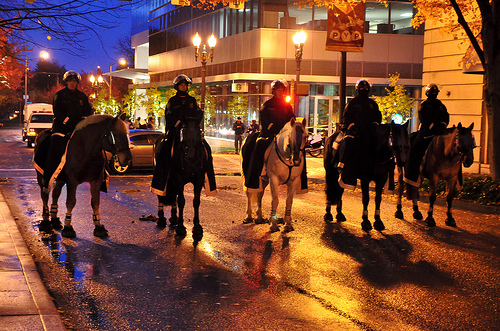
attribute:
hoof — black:
[86, 222, 116, 243]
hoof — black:
[441, 212, 458, 232]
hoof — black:
[354, 215, 376, 237]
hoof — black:
[274, 223, 294, 240]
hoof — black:
[184, 221, 209, 243]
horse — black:
[152, 103, 210, 235]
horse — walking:
[152, 113, 214, 238]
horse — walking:
[239, 120, 311, 230]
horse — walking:
[397, 123, 477, 223]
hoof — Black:
[319, 205, 334, 219]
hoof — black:
[446, 215, 460, 230]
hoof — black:
[266, 222, 281, 233]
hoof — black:
[361, 218, 372, 235]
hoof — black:
[92, 219, 107, 239]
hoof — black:
[393, 212, 405, 222]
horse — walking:
[31, 111, 135, 237]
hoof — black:
[53, 223, 82, 238]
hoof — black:
[38, 218, 50, 230]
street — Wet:
[0, 113, 496, 329]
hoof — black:
[362, 219, 384, 230]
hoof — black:
[321, 210, 347, 220]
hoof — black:
[425, 213, 435, 226]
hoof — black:
[176, 221, 206, 238]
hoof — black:
[63, 224, 77, 237]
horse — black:
[150, 100, 217, 251]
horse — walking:
[21, 107, 139, 239]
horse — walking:
[148, 107, 215, 242]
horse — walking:
[238, 115, 311, 236]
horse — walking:
[319, 115, 411, 237]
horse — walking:
[395, 114, 478, 230]